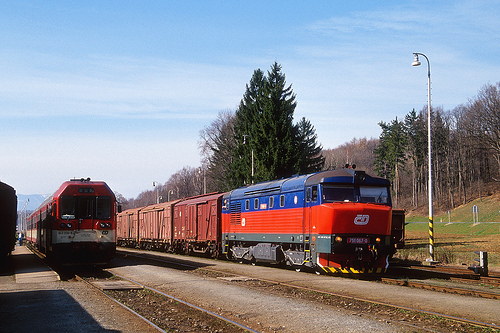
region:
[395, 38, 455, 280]
tall light pole on side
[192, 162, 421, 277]
red and blue train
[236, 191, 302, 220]
four windows on train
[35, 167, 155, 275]
train with red face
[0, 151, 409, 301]
three trains parked on tracks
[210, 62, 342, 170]
large green tree in background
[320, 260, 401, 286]
yellow and black markings on train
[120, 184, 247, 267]
red cable cars on train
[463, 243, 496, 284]
small metal piece on side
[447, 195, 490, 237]
green grass in distance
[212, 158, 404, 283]
red and blue train engine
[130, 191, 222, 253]
red train cargo cars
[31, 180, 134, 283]
red train on tracks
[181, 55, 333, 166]
brown tree with green leaves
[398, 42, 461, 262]
silver, black and yellow light post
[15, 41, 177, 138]
white clouds against blue sky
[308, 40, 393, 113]
white clouds against blue sky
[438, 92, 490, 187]
brown trees near train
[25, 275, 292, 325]
silver worn train tracks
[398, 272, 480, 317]
silver worn train tracks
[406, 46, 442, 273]
light pole by a train track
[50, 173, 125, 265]
front of a train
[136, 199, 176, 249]
a red train car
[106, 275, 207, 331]
a train track in a train yard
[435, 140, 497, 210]
trees on a hill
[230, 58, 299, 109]
top of a a tree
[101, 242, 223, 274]
a shadow of a train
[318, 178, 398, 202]
front window of a train engine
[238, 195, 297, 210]
windows on the side of a train engin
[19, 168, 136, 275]
train on tracks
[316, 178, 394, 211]
front windshield on a train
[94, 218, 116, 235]
front lights on a train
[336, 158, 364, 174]
horn on top of a train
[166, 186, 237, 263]
boxcar behind a train engine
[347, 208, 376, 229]
logo on the front of a train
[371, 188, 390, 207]
front windshield wiper on a train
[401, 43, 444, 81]
light on a pole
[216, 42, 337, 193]
green tree behind a train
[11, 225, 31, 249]
person standing near a train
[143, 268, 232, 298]
clear surface on track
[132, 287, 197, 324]
pebbles on train track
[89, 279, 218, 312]
large gray train track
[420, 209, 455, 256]
yellow and black portion of light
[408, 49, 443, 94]
curved edge of large lighting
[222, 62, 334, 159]
curved top of green tree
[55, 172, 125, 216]
red top of train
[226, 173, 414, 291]
red and blue train car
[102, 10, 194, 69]
blue skies overhead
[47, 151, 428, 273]
pair of trains on the track